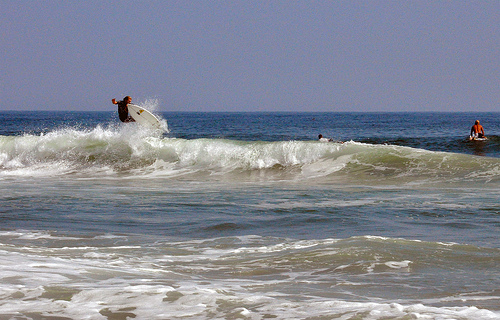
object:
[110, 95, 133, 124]
man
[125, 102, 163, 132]
surfboard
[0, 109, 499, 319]
water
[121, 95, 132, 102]
head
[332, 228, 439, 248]
wave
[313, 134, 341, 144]
people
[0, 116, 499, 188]
wave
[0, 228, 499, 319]
waves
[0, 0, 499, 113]
sky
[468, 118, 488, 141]
man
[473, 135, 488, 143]
surfboard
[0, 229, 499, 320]
bubble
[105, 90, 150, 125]
midair